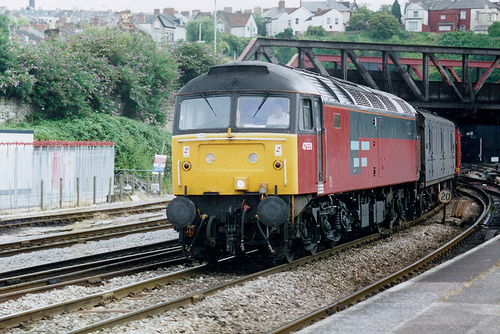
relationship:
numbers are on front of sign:
[440, 192, 452, 203] [437, 189, 456, 224]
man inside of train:
[265, 101, 296, 135] [155, 58, 480, 259]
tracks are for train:
[37, 241, 184, 319] [155, 58, 480, 259]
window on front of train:
[178, 94, 295, 132] [155, 58, 480, 259]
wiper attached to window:
[251, 95, 274, 115] [178, 94, 295, 132]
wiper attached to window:
[195, 87, 220, 116] [178, 94, 295, 132]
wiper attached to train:
[251, 95, 274, 115] [155, 58, 480, 259]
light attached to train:
[231, 176, 252, 194] [155, 58, 480, 259]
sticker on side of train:
[301, 138, 317, 155] [155, 58, 480, 259]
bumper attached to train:
[167, 194, 293, 228] [155, 58, 480, 259]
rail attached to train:
[323, 126, 333, 183] [155, 58, 480, 259]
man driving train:
[265, 101, 296, 135] [155, 58, 480, 259]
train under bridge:
[155, 58, 480, 259] [337, 41, 499, 108]